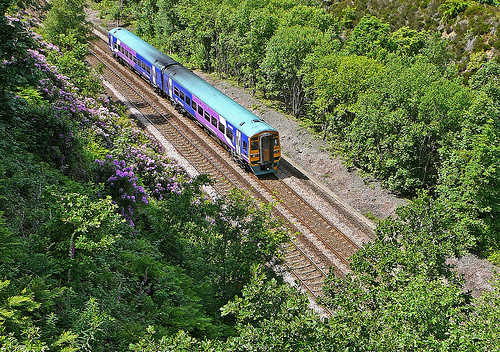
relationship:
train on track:
[139, 55, 283, 173] [267, 175, 375, 272]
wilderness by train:
[193, 23, 437, 171] [139, 55, 283, 173]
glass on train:
[168, 88, 255, 136] [139, 55, 283, 173]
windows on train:
[121, 47, 165, 68] [109, 27, 280, 176]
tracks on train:
[256, 182, 372, 322] [139, 55, 283, 173]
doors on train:
[222, 124, 250, 165] [139, 55, 283, 173]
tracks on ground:
[256, 182, 372, 322] [210, 192, 441, 302]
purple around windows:
[122, 51, 173, 100] [121, 47, 165, 68]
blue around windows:
[166, 85, 195, 114] [121, 47, 165, 68]